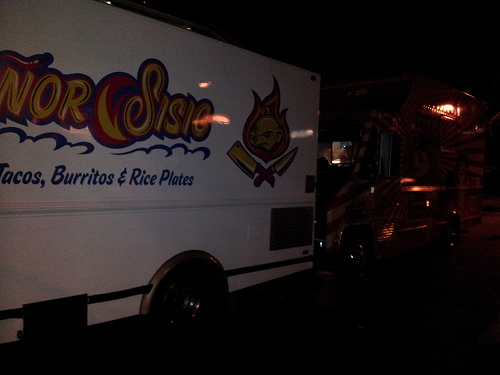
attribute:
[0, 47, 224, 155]
logo — business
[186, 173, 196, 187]
letter — blue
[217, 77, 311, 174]
flames — red and yellow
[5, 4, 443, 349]
truck — food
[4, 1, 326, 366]
white truck — large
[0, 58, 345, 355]
bus — white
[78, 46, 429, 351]
bus — white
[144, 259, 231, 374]
wheel — black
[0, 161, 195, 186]
lettering — blue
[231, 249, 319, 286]
stripe — black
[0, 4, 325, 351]
truck — food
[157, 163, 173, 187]
letter — blue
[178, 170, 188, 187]
letter — blue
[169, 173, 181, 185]
letter — blue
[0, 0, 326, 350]
bus — white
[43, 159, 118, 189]
letter — blue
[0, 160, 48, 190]
letter — blue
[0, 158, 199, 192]
letter — blue